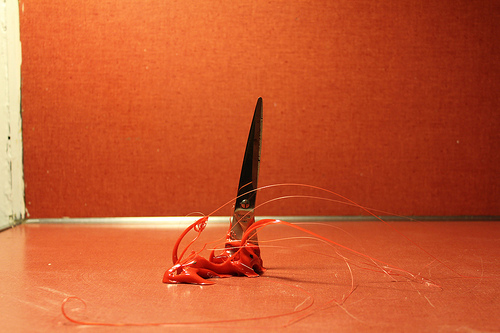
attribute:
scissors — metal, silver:
[229, 96, 265, 229]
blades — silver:
[235, 96, 266, 208]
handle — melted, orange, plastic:
[63, 182, 445, 328]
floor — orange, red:
[1, 218, 500, 331]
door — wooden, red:
[21, 4, 499, 218]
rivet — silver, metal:
[241, 199, 251, 208]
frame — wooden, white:
[3, 1, 26, 231]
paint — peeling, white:
[3, 3, 23, 230]